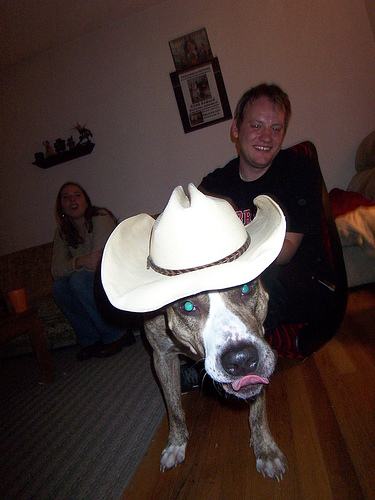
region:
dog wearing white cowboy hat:
[85, 184, 314, 489]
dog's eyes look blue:
[108, 197, 311, 414]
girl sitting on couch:
[31, 172, 147, 376]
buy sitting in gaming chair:
[190, 95, 363, 376]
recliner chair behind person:
[266, 116, 372, 303]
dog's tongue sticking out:
[140, 280, 302, 490]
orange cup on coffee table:
[3, 271, 78, 382]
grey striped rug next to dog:
[14, 331, 256, 496]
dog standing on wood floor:
[136, 307, 331, 496]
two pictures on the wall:
[148, 10, 255, 162]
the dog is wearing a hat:
[110, 214, 288, 354]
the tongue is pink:
[234, 370, 269, 393]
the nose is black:
[217, 342, 260, 373]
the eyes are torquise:
[179, 295, 198, 315]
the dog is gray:
[154, 327, 173, 351]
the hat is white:
[179, 213, 210, 230]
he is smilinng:
[248, 136, 275, 155]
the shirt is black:
[221, 173, 249, 196]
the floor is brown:
[298, 411, 344, 450]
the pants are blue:
[59, 294, 85, 320]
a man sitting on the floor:
[179, 82, 350, 402]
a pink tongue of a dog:
[231, 371, 269, 390]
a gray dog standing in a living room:
[142, 277, 289, 478]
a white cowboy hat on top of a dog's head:
[101, 180, 285, 311]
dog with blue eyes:
[181, 284, 251, 311]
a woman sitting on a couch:
[50, 179, 136, 357]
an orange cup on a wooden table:
[7, 286, 28, 315]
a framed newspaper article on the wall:
[162, 56, 234, 131]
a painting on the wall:
[164, 26, 213, 68]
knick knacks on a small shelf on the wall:
[30, 122, 94, 167]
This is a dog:
[178, 269, 321, 463]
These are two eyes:
[174, 293, 294, 320]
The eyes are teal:
[145, 288, 274, 324]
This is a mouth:
[188, 352, 370, 440]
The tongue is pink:
[227, 381, 286, 435]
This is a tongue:
[256, 342, 266, 414]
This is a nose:
[210, 345, 326, 424]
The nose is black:
[213, 328, 269, 385]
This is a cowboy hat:
[156, 217, 190, 257]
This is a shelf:
[38, 143, 108, 152]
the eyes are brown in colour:
[149, 262, 284, 328]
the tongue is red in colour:
[193, 323, 306, 434]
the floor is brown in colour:
[280, 376, 354, 481]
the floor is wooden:
[302, 420, 361, 481]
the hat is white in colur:
[96, 176, 337, 328]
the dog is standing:
[84, 188, 331, 482]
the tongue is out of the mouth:
[183, 345, 311, 418]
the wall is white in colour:
[270, 2, 353, 79]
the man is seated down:
[192, 71, 348, 330]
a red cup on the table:
[4, 273, 40, 323]